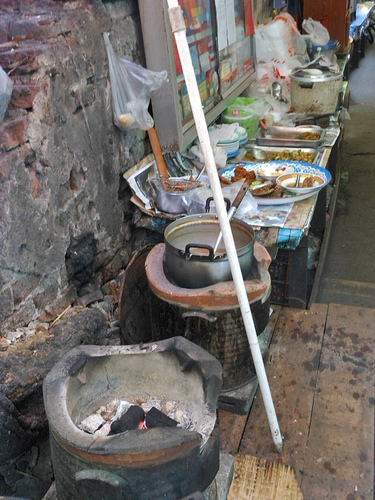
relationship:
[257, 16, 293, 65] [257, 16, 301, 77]
bag of plates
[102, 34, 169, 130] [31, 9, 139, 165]
bag hanging from wall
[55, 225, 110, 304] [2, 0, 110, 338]
break in wall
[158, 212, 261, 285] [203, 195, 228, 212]
pot with handles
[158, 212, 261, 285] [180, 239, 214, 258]
pot with handles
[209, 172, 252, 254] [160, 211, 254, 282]
laddle in pot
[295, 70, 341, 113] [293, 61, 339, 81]
pot with lid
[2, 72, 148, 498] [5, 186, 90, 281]
wall made of bricks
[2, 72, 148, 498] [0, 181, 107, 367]
wall made of cement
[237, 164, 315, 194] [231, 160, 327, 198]
food in bowl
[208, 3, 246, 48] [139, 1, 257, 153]
papers in bulletin board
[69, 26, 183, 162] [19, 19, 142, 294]
bag on wall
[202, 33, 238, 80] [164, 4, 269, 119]
glass encased bulletin board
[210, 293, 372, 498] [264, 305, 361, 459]
planks on ground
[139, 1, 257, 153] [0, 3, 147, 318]
bulletin board against wall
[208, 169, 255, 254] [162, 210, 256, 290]
spoon in a pot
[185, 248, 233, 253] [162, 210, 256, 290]
soup in a pot